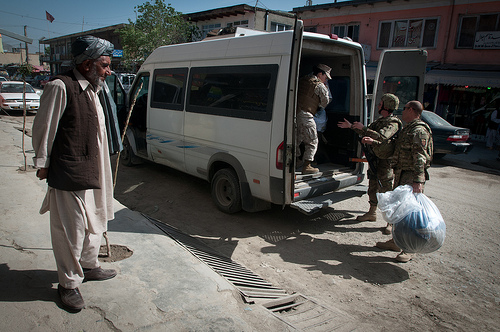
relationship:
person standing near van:
[375, 101, 434, 262] [118, 31, 363, 216]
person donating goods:
[375, 101, 434, 262] [375, 188, 459, 255]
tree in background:
[118, 1, 209, 148] [2, 2, 493, 156]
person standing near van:
[31, 39, 145, 311] [118, 31, 363, 216]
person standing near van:
[393, 97, 434, 263] [118, 31, 363, 216]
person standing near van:
[352, 92, 398, 232] [118, 31, 363, 216]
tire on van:
[200, 159, 246, 222] [118, 31, 363, 216]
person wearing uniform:
[393, 97, 434, 263] [396, 122, 435, 242]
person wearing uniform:
[352, 92, 398, 232] [353, 113, 398, 214]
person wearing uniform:
[294, 54, 338, 173] [289, 78, 330, 168]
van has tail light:
[118, 31, 363, 216] [271, 135, 291, 174]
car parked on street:
[2, 65, 44, 113] [4, 85, 487, 327]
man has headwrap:
[31, 39, 145, 311] [70, 35, 118, 64]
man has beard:
[31, 39, 145, 311] [85, 62, 107, 89]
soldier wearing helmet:
[352, 92, 398, 232] [370, 92, 400, 111]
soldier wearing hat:
[294, 54, 338, 173] [315, 61, 337, 80]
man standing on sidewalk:
[31, 39, 145, 311] [1, 140, 253, 331]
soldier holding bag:
[393, 97, 434, 263] [375, 188, 459, 255]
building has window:
[283, 3, 499, 153] [378, 20, 437, 50]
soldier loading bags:
[352, 92, 398, 232] [375, 188, 459, 255]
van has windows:
[118, 31, 363, 216] [153, 65, 280, 120]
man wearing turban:
[31, 39, 145, 311] [70, 35, 118, 64]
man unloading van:
[352, 92, 398, 232] [118, 31, 363, 216]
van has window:
[118, 31, 363, 216] [153, 65, 280, 120]